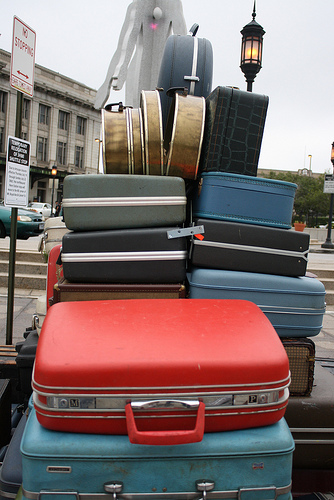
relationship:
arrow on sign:
[10, 61, 34, 77] [8, 13, 52, 152]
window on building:
[37, 100, 55, 128] [0, 48, 105, 221]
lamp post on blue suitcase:
[238, 0, 267, 91] [196, 172, 298, 230]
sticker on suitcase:
[194, 231, 205, 241] [185, 204, 315, 285]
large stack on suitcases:
[1, 17, 332, 498] [6, 14, 327, 496]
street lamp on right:
[218, 34, 290, 98] [275, 67, 309, 116]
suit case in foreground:
[22, 287, 281, 418] [45, 447, 330, 498]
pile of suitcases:
[48, 263, 303, 495] [0, 83, 324, 488]